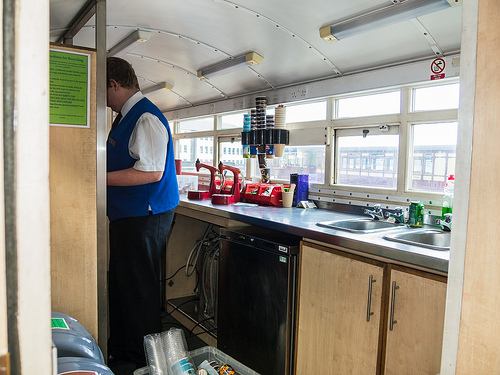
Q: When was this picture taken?
A: In the day.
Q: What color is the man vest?
A: Royal blue.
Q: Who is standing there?
A: A man.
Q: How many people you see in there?
A: Only one.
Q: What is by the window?
A: Dish detergent.